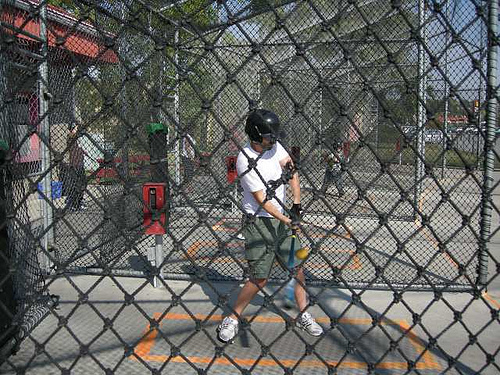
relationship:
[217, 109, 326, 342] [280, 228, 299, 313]
boy swing bat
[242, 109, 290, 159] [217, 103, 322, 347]
head on batter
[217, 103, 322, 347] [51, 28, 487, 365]
batter in cage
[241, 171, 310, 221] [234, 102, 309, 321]
arms on batter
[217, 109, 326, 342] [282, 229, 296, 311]
boy swinging bat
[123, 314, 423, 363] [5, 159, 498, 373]
lines on ground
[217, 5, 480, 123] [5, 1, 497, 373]
sky above cages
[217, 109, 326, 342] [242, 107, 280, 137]
boy wears helmet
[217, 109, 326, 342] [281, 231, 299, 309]
boy holding bat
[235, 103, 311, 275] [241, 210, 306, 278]
boy wearing shorts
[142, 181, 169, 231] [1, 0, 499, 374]
box behind fence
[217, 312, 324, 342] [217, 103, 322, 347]
shoes of batter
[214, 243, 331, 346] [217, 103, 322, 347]
legs of batter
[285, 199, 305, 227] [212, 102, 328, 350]
glove worn by batter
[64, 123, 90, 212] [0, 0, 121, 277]
person watching from cages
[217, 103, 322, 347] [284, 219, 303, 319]
batter swinging bat